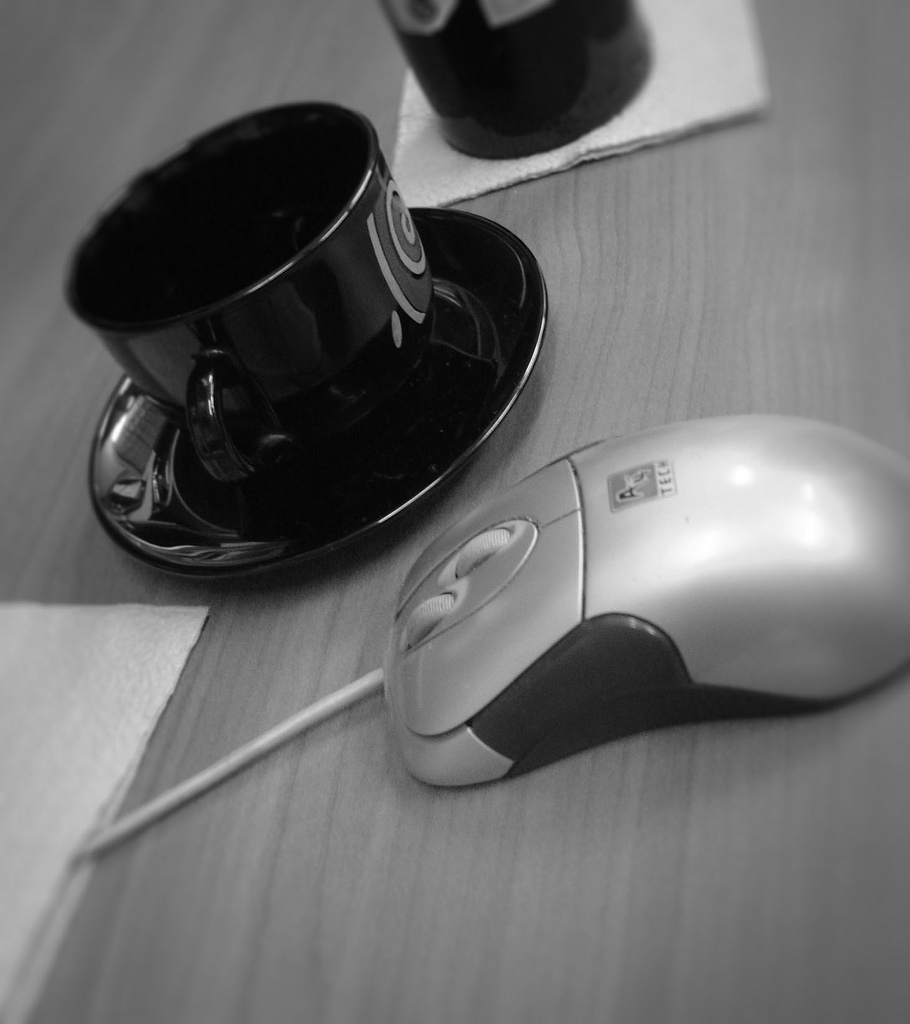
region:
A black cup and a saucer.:
[51, 98, 577, 605]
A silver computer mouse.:
[349, 406, 906, 805]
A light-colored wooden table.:
[225, 857, 908, 1014]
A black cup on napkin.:
[388, 2, 740, 169]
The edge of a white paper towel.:
[665, 6, 847, 143]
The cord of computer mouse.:
[65, 657, 377, 802]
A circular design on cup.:
[341, 153, 463, 335]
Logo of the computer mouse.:
[596, 451, 724, 529]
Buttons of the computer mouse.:
[390, 451, 570, 713]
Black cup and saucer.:
[57, 149, 488, 592]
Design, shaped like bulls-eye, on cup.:
[341, 210, 484, 379]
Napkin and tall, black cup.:
[369, 24, 798, 238]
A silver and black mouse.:
[374, 344, 891, 765]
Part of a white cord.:
[62, 774, 429, 907]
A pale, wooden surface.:
[148, 663, 830, 1019]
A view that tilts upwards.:
[55, 41, 824, 986]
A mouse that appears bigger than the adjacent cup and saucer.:
[66, 253, 896, 760]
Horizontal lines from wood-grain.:
[163, 830, 857, 999]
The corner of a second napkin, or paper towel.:
[0, 594, 375, 981]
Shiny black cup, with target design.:
[84, 108, 435, 472]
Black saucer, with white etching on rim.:
[98, 437, 423, 585]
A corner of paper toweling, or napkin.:
[9, 587, 239, 1010]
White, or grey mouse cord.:
[76, 673, 389, 884]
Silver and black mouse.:
[383, 407, 893, 778]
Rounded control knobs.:
[397, 530, 554, 679]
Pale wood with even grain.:
[236, 831, 826, 1006]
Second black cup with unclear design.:
[362, 2, 724, 216]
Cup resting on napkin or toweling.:
[401, 51, 768, 220]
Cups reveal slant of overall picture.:
[44, 15, 716, 624]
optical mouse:
[383, 408, 905, 786]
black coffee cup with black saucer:
[68, 100, 552, 587]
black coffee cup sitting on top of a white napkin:
[380, 1, 770, 212]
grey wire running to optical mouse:
[73, 660, 382, 862]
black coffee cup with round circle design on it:
[61, 98, 436, 499]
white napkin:
[2, 601, 212, 1014]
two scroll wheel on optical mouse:
[390, 525, 538, 643]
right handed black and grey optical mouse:
[377, 410, 906, 789]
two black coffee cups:
[67, 2, 652, 490]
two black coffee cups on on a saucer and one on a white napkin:
[68, 3, 773, 578]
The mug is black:
[61, 180, 453, 468]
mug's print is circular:
[354, 178, 451, 334]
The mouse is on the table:
[401, 534, 883, 796]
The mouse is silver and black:
[395, 533, 870, 796]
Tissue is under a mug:
[385, 36, 801, 208]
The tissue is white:
[388, 42, 758, 216]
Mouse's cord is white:
[77, 759, 373, 882]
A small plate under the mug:
[96, 366, 489, 584]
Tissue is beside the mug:
[20, 607, 195, 968]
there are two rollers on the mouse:
[388, 539, 566, 670]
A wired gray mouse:
[347, 430, 907, 657]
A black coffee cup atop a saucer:
[56, 116, 525, 600]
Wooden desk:
[135, 819, 756, 997]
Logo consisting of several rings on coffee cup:
[347, 157, 470, 354]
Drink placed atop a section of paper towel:
[363, 4, 862, 221]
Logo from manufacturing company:
[589, 459, 709, 540]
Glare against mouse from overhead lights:
[676, 461, 891, 618]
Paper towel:
[0, 613, 167, 1008]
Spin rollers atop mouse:
[393, 546, 585, 640]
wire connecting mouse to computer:
[102, 634, 382, 869]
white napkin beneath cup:
[395, 128, 643, 181]